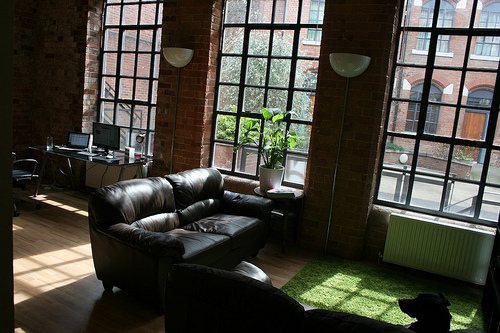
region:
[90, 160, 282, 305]
Black leather sofa next to white pot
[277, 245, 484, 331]
Green rug in front of black leather sofa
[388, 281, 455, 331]
Dog sitting on black leather sofa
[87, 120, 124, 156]
Monitor on desk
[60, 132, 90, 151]
Laptop next to monitor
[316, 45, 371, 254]
Large lamp leaning on brick wall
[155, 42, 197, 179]
Large lamp leaning on brick wall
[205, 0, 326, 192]
Large window behind plant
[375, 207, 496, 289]
White heater against wall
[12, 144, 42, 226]
Chair in front of desk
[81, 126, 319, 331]
love seat couch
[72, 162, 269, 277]
leather brown love seat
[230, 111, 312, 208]
plant near window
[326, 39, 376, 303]
tall lamp near brick wall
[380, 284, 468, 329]
dog looking at couch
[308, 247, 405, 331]
green carpet on floor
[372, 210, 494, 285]
white colored heater near wall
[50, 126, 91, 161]
laptop computer on desktop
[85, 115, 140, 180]
desktop computer on desk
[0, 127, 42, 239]
computer chair near desk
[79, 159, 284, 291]
a black couch in a room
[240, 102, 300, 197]
a white pot in front a window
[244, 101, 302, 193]
a green plant in a white pot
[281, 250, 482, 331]
a green rug on the floor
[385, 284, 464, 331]
a dog on the floor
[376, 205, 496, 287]
a heater in front a window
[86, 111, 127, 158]
screen of a computer over a table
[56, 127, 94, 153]
a laptop is next to a screen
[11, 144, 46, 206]
a chair in front a table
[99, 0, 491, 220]
room has tall windows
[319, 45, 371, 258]
a tall floor lamp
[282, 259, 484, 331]
an area of green turf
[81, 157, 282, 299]
a leather sofa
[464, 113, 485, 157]
a brown wooden door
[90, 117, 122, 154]
a flat computer monitor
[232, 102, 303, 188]
a large green plant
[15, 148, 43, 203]
part of a computer chair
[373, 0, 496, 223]
a large window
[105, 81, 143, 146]
a black stair rail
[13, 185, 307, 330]
light brown hardwood floor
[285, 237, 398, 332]
green shag carpet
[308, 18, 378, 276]
metal standing lamp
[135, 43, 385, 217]
two metal pole standing lamps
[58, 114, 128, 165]
personal computer with power on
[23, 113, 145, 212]
table with computer on it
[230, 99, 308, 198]
green plant in front of window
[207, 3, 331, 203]
multi panel window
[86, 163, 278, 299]
black leather loveseat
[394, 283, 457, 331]
black shorthaired dog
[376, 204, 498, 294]
white radiator heater under window